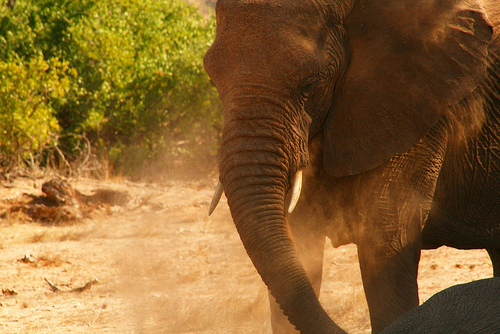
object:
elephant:
[203, 0, 500, 331]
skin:
[311, 119, 414, 171]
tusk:
[287, 169, 304, 215]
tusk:
[209, 180, 222, 218]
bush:
[0, 53, 86, 182]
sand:
[119, 181, 218, 229]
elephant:
[372, 275, 499, 333]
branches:
[8, 127, 68, 185]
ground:
[9, 166, 490, 326]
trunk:
[219, 93, 351, 333]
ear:
[316, 2, 493, 180]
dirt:
[14, 170, 109, 230]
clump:
[22, 250, 92, 298]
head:
[201, 1, 361, 333]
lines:
[472, 49, 497, 79]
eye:
[304, 80, 319, 91]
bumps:
[277, 35, 320, 78]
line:
[225, 83, 290, 95]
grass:
[13, 222, 77, 245]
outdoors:
[4, 104, 494, 334]